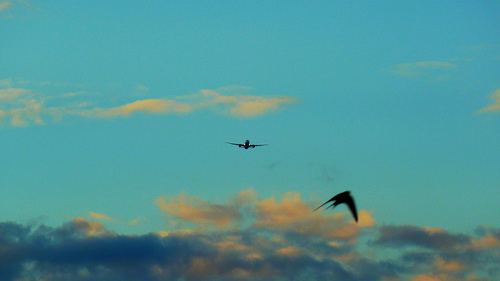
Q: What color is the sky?
A: Blue.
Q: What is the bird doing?
A: Flying.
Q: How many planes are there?
A: One.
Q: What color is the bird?
A: Black.